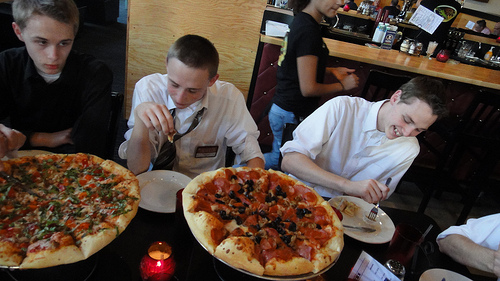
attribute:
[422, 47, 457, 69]
candle — red 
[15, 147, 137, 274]
pie — whole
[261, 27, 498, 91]
counter — wooden 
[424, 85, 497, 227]
stool — black 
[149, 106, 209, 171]
tie — loose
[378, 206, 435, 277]
glass — red 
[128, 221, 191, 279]
candle — lit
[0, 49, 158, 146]
tee shirt — black 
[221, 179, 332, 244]
olives — black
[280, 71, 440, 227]
boy — leaning over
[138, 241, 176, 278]
candle holder — red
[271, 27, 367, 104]
woman's shirt — black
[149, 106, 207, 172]
necktie — loose, pulled out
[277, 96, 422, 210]
shirt — white 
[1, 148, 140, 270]
pizzas — large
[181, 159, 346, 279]
pizzas — large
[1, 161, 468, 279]
table — black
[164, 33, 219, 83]
hair — brown 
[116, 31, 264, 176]
man — wearing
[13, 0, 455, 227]
men — young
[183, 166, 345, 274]
pizza — not cut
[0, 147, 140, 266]
pizza — not cut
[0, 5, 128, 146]
area — dark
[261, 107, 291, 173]
jeans — blue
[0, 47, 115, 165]
shirt — black